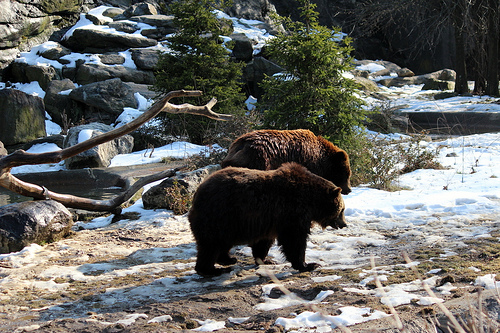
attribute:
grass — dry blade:
[400, 250, 491, 332]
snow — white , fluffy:
[345, 130, 499, 217]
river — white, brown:
[375, 100, 496, 155]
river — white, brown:
[359, 193, 473, 250]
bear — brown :
[227, 131, 367, 180]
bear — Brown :
[218, 126, 353, 195]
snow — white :
[350, 185, 499, 244]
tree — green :
[250, 4, 393, 196]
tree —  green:
[257, 2, 371, 184]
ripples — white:
[79, 183, 98, 200]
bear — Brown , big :
[187, 163, 348, 278]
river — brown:
[0, 107, 492, 224]